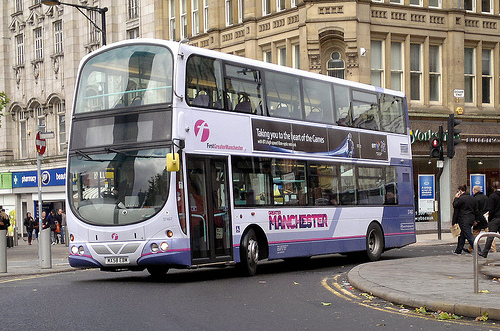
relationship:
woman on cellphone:
[440, 176, 476, 268] [452, 189, 462, 197]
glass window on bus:
[219, 67, 284, 118] [62, 35, 417, 275]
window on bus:
[255, 72, 302, 113] [62, 35, 417, 275]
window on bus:
[302, 79, 331, 124] [62, 35, 417, 275]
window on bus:
[327, 80, 356, 128] [62, 35, 417, 275]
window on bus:
[352, 85, 381, 128] [66, 38, 416, 278]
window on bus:
[366, 84, 411, 141] [20, 24, 465, 311]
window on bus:
[230, 151, 271, 207] [62, 35, 417, 275]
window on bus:
[272, 163, 313, 212] [66, 38, 416, 278]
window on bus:
[305, 164, 339, 210] [37, 22, 495, 297]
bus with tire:
[37, 22, 495, 297] [234, 230, 274, 264]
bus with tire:
[37, 22, 495, 297] [363, 223, 383, 257]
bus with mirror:
[66, 38, 416, 278] [163, 155, 185, 183]